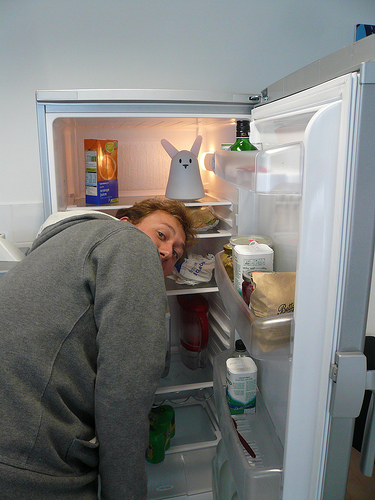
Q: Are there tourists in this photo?
A: No, there are no tourists.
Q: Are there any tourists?
A: No, there are no tourists.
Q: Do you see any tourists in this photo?
A: No, there are no tourists.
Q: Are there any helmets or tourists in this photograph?
A: No, there are no tourists or helmets.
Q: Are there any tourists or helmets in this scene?
A: No, there are no tourists or helmets.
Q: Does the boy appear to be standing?
A: Yes, the boy is standing.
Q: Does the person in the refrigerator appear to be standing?
A: Yes, the boy is standing.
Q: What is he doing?
A: The boy is standing.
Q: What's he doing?
A: The boy is standing.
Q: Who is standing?
A: The boy is standing.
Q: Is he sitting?
A: No, the boy is standing.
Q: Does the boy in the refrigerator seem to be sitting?
A: No, the boy is standing.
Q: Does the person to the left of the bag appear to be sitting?
A: No, the boy is standing.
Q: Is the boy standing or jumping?
A: The boy is standing.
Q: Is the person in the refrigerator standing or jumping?
A: The boy is standing.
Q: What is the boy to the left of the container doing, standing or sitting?
A: The boy is standing.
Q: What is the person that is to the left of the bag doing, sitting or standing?
A: The boy is standing.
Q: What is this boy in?
A: The boy is in the freezer.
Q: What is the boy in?
A: The boy is in the freezer.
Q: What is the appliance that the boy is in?
A: The appliance is a refrigerator.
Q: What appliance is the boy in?
A: The boy is in the freezer.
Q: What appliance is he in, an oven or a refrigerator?
A: The boy is in a refrigerator.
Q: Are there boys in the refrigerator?
A: Yes, there is a boy in the refrigerator.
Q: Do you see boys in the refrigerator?
A: Yes, there is a boy in the refrigerator.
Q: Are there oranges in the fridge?
A: No, there is a boy in the fridge.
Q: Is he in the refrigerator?
A: Yes, the boy is in the refrigerator.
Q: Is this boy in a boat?
A: No, the boy is in the refrigerator.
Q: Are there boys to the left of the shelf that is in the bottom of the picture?
A: Yes, there is a boy to the left of the shelf.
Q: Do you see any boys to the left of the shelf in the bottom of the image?
A: Yes, there is a boy to the left of the shelf.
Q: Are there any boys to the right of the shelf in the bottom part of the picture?
A: No, the boy is to the left of the shelf.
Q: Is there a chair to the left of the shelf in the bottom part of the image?
A: No, there is a boy to the left of the shelf.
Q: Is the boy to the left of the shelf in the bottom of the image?
A: Yes, the boy is to the left of the shelf.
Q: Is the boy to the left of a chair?
A: No, the boy is to the left of the shelf.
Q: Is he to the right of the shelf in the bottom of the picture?
A: No, the boy is to the left of the shelf.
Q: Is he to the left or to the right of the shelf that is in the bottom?
A: The boy is to the left of the shelf.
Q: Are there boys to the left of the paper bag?
A: Yes, there is a boy to the left of the bag.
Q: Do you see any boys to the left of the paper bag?
A: Yes, there is a boy to the left of the bag.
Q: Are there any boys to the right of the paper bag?
A: No, the boy is to the left of the bag.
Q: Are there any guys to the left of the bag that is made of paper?
A: No, there is a boy to the left of the bag.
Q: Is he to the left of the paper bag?
A: Yes, the boy is to the left of the bag.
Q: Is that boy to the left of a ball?
A: No, the boy is to the left of the bag.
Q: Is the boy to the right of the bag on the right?
A: No, the boy is to the left of the bag.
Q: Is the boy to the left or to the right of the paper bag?
A: The boy is to the left of the bag.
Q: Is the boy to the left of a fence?
A: No, the boy is to the left of the container.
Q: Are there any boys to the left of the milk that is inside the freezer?
A: Yes, there is a boy to the left of the milk.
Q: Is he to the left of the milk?
A: Yes, the boy is to the left of the milk.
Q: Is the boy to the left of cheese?
A: No, the boy is to the left of the milk.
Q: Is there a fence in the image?
A: No, there are no fences.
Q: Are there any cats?
A: Yes, there is a cat.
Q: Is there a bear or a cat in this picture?
A: Yes, there is a cat.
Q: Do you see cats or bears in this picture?
A: Yes, there is a cat.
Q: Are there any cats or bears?
A: Yes, there is a cat.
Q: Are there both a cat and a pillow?
A: No, there is a cat but no pillows.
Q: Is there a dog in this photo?
A: No, there are no dogs.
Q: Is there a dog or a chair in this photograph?
A: No, there are no dogs or chairs.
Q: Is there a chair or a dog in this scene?
A: No, there are no dogs or chairs.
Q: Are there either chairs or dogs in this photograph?
A: No, there are no dogs or chairs.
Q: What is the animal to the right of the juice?
A: The animal is a cat.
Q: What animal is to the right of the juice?
A: The animal is a cat.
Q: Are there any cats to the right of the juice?
A: Yes, there is a cat to the right of the juice.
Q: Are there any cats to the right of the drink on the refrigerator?
A: Yes, there is a cat to the right of the juice.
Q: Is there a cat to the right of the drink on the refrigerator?
A: Yes, there is a cat to the right of the juice.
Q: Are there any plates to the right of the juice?
A: No, there is a cat to the right of the juice.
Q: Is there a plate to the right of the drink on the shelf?
A: No, there is a cat to the right of the juice.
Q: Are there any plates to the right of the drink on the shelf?
A: No, there is a cat to the right of the juice.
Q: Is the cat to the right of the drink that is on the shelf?
A: Yes, the cat is to the right of the juice.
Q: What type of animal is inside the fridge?
A: The animal is a cat.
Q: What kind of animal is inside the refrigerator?
A: The animal is a cat.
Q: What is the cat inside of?
A: The cat is inside the fridge.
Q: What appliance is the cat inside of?
A: The cat is inside the refrigerator.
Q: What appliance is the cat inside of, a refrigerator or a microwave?
A: The cat is inside a refrigerator.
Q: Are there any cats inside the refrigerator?
A: Yes, there is a cat inside the refrigerator.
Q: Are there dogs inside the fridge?
A: No, there is a cat inside the fridge.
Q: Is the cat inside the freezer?
A: Yes, the cat is inside the freezer.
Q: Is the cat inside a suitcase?
A: No, the cat is inside the freezer.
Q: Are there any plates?
A: No, there are no plates.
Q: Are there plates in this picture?
A: No, there are no plates.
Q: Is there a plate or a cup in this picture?
A: No, there are no plates or cups.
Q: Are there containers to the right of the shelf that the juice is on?
A: Yes, there is a container to the right of the shelf.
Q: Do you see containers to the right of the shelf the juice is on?
A: Yes, there is a container to the right of the shelf.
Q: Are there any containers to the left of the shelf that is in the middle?
A: No, the container is to the right of the shelf.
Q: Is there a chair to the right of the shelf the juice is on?
A: No, there is a container to the right of the shelf.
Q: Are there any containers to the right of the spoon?
A: Yes, there is a container to the right of the spoon.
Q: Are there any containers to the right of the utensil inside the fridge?
A: Yes, there is a container to the right of the spoon.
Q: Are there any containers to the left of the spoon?
A: No, the container is to the right of the spoon.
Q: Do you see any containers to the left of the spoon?
A: No, the container is to the right of the spoon.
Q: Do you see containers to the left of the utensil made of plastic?
A: No, the container is to the right of the spoon.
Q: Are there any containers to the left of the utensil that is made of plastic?
A: No, the container is to the right of the spoon.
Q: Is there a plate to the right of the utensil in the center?
A: No, there is a container to the right of the spoon.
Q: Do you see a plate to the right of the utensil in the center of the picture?
A: No, there is a container to the right of the spoon.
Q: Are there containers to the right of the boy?
A: Yes, there is a container to the right of the boy.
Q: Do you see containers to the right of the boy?
A: Yes, there is a container to the right of the boy.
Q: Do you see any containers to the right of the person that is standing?
A: Yes, there is a container to the right of the boy.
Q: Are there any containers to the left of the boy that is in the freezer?
A: No, the container is to the right of the boy.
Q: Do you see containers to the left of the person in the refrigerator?
A: No, the container is to the right of the boy.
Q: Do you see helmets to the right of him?
A: No, there is a container to the right of the boy.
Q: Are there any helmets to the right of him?
A: No, there is a container to the right of the boy.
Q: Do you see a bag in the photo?
A: Yes, there is a bag.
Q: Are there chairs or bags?
A: Yes, there is a bag.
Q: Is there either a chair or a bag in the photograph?
A: Yes, there is a bag.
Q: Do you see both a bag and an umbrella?
A: No, there is a bag but no umbrellas.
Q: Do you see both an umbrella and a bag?
A: No, there is a bag but no umbrellas.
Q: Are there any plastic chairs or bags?
A: Yes, there is a plastic bag.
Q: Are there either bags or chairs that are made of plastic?
A: Yes, the bag is made of plastic.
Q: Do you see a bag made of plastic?
A: Yes, there is a bag that is made of plastic.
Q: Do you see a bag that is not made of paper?
A: Yes, there is a bag that is made of plastic.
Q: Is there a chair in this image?
A: No, there are no chairs.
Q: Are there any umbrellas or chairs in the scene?
A: No, there are no chairs or umbrellas.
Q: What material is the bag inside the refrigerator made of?
A: The bag is made of plastic.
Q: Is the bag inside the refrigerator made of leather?
A: No, the bag is made of plastic.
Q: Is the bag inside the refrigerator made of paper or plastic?
A: The bag is made of plastic.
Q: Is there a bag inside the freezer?
A: Yes, there is a bag inside the freezer.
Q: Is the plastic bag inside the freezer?
A: Yes, the bag is inside the freezer.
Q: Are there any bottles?
A: Yes, there is a bottle.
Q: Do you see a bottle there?
A: Yes, there is a bottle.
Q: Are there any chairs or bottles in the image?
A: Yes, there is a bottle.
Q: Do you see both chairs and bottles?
A: No, there is a bottle but no chairs.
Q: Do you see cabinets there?
A: No, there are no cabinets.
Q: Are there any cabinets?
A: No, there are no cabinets.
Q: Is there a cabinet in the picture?
A: No, there are no cabinets.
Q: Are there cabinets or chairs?
A: No, there are no cabinets or chairs.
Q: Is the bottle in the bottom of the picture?
A: No, the bottle is in the top of the image.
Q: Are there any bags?
A: Yes, there is a bag.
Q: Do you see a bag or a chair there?
A: Yes, there is a bag.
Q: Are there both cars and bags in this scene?
A: No, there is a bag but no cars.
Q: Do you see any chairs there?
A: No, there are no chairs.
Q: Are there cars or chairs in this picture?
A: No, there are no chairs or cars.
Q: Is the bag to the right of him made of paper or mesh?
A: The bag is made of paper.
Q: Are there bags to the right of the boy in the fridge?
A: Yes, there is a bag to the right of the boy.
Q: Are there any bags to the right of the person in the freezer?
A: Yes, there is a bag to the right of the boy.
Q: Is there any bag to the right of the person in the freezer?
A: Yes, there is a bag to the right of the boy.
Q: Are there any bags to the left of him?
A: No, the bag is to the right of the boy.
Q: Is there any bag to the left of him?
A: No, the bag is to the right of the boy.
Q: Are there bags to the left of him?
A: No, the bag is to the right of the boy.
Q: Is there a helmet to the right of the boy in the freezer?
A: No, there is a bag to the right of the boy.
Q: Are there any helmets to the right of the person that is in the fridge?
A: No, there is a bag to the right of the boy.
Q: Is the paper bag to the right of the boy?
A: Yes, the bag is to the right of the boy.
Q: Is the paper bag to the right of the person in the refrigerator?
A: Yes, the bag is to the right of the boy.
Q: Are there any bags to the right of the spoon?
A: Yes, there is a bag to the right of the spoon.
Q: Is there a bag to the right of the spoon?
A: Yes, there is a bag to the right of the spoon.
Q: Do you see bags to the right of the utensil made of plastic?
A: Yes, there is a bag to the right of the spoon.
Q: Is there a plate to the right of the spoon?
A: No, there is a bag to the right of the spoon.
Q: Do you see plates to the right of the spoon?
A: No, there is a bag to the right of the spoon.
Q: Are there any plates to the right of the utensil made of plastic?
A: No, there is a bag to the right of the spoon.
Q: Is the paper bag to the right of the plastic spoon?
A: Yes, the bag is to the right of the spoon.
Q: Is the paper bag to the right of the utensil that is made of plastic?
A: Yes, the bag is to the right of the spoon.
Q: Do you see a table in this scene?
A: No, there are no tables.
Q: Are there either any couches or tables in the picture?
A: No, there are no tables or couches.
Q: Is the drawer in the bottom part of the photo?
A: Yes, the drawer is in the bottom of the image.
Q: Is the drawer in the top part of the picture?
A: No, the drawer is in the bottom of the image.